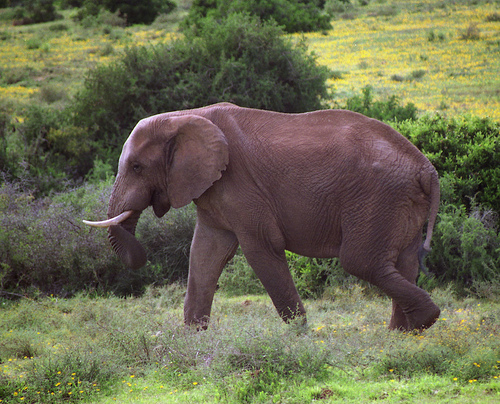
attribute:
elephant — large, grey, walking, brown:
[81, 100, 445, 336]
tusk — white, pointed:
[79, 210, 133, 231]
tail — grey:
[422, 161, 438, 253]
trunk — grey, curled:
[109, 177, 151, 270]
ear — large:
[155, 115, 230, 220]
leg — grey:
[224, 199, 309, 339]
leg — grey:
[182, 211, 237, 330]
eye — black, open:
[131, 162, 142, 172]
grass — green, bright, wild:
[1, 0, 499, 402]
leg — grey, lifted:
[338, 198, 442, 334]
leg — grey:
[391, 226, 424, 335]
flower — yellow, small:
[128, 373, 137, 379]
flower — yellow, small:
[71, 372, 77, 377]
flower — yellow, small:
[57, 371, 62, 376]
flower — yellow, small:
[389, 368, 394, 372]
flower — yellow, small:
[453, 378, 457, 382]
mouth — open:
[135, 189, 167, 217]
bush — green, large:
[65, 9, 336, 176]